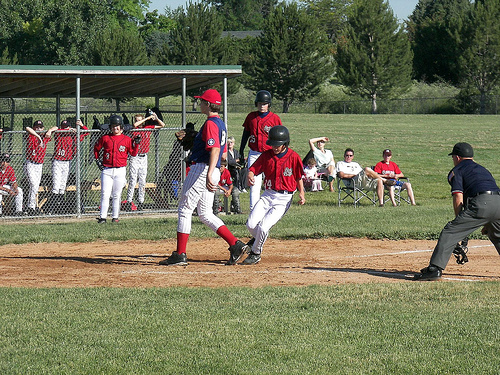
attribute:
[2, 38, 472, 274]
game — baseball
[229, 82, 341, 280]
player — running, red, baseball, wearing, wearing helmet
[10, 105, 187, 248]
team — waiting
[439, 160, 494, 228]
uniform — gray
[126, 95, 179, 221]
player — leaning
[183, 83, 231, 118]
hat — red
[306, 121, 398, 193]
people — sitting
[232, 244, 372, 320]
ball — base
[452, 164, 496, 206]
shirt — black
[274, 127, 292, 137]
helmet — black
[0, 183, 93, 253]
fans — sitting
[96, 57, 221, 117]
dugout — green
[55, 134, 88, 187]
fence — metal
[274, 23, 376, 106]
tree — green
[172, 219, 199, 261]
sock — red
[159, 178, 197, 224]
pant — white, baseball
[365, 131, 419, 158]
grass — green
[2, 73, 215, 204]
spectators — sitting